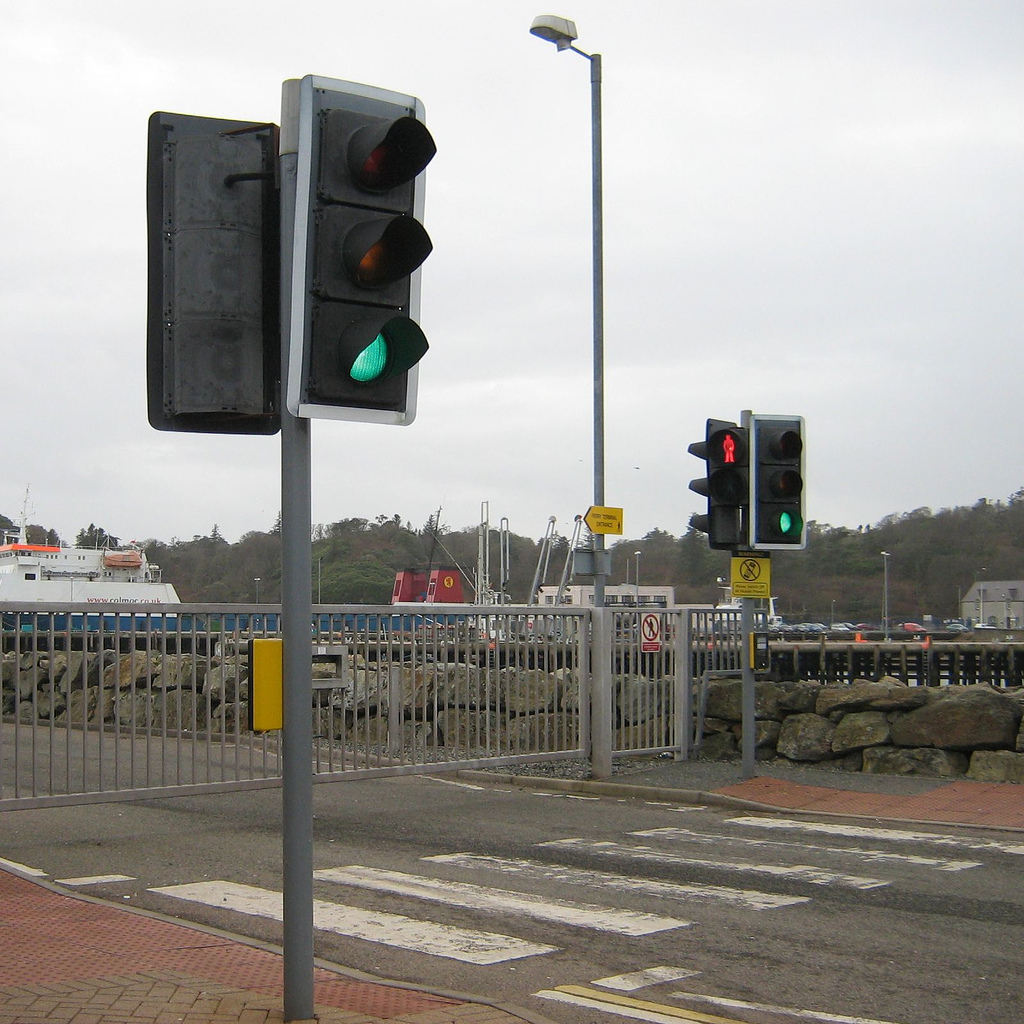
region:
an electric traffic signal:
[274, 77, 439, 425]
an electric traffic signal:
[748, 413, 810, 549]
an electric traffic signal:
[688, 418, 740, 549]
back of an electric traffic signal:
[148, 111, 282, 434]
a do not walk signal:
[707, 428, 749, 506]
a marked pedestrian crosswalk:
[151, 817, 1017, 969]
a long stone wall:
[2, 653, 1023, 783]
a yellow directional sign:
[582, 508, 627, 534]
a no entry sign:
[638, 611, 665, 656]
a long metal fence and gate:
[0, 601, 748, 830]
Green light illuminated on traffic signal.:
[326, 316, 419, 393]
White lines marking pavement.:
[360, 774, 902, 934]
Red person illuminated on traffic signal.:
[699, 432, 744, 470]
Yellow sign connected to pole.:
[726, 554, 774, 596]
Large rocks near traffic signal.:
[713, 682, 1012, 768]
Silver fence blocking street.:
[32, 610, 612, 747]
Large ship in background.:
[18, 547, 202, 612]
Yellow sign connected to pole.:
[578, 505, 633, 543]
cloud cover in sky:
[1, 3, 1017, 535]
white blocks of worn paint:
[150, 815, 1021, 970]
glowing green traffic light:
[759, 416, 805, 549]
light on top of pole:
[529, 14, 603, 505]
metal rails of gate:
[4, 604, 735, 814]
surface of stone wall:
[8, 650, 1021, 783]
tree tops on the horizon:
[0, 489, 1019, 604]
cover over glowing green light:
[339, 314, 429, 388]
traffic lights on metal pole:
[137, 72, 438, 1021]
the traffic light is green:
[213, 7, 476, 494]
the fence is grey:
[7, 532, 663, 807]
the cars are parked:
[694, 599, 992, 651]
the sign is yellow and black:
[686, 541, 779, 609]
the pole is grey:
[228, 433, 347, 999]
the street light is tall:
[512, 0, 642, 634]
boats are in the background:
[2, 501, 799, 642]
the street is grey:
[791, 877, 992, 996]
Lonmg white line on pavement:
[554, 827, 884, 900]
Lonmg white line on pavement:
[423, 843, 810, 914]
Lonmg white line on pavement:
[314, 845, 685, 940]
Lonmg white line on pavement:
[145, 872, 558, 981]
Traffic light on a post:
[269, 59, 437, 432]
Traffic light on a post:
[134, 112, 283, 442]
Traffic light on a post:
[690, 403, 811, 563]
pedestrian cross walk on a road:
[125, 797, 1011, 985]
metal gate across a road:
[7, 595, 751, 815]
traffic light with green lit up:
[279, 75, 434, 427]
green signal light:
[287, 70, 452, 421]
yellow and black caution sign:
[569, 499, 643, 556]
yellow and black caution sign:
[715, 550, 772, 598]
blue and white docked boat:
[13, 521, 192, 645]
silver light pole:
[519, 2, 643, 446]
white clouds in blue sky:
[626, 63, 719, 210]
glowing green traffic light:
[291, 75, 438, 423]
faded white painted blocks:
[150, 818, 1018, 965]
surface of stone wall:
[7, 650, 1020, 778]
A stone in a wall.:
[833, 703, 892, 752]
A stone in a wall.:
[778, 683, 839, 713]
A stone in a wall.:
[773, 706, 834, 764]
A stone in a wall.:
[846, 741, 965, 783]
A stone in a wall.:
[884, 687, 1014, 748]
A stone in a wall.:
[495, 672, 572, 710]